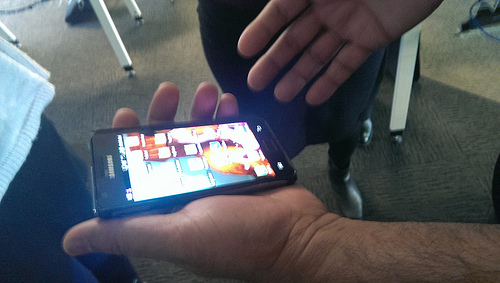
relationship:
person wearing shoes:
[192, 14, 383, 213] [329, 151, 363, 211]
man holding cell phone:
[73, 157, 479, 277] [70, 87, 341, 217]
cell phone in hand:
[70, 87, 341, 217] [61, 71, 349, 267]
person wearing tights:
[192, 14, 383, 213] [308, 116, 362, 179]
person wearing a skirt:
[192, 14, 383, 213] [174, 14, 372, 141]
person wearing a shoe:
[192, 14, 383, 213] [323, 148, 359, 216]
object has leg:
[347, 18, 428, 137] [361, 28, 430, 150]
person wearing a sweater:
[8, 45, 138, 271] [3, 29, 48, 204]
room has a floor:
[9, 14, 480, 273] [11, 16, 432, 186]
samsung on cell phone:
[90, 148, 127, 191] [70, 87, 341, 217]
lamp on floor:
[0, 5, 64, 34] [11, 16, 432, 186]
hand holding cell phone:
[61, 71, 349, 267] [70, 87, 341, 217]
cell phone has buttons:
[70, 87, 341, 217] [258, 108, 310, 179]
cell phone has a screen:
[70, 87, 341, 217] [117, 114, 243, 204]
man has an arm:
[73, 157, 479, 277] [259, 195, 490, 283]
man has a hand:
[73, 157, 479, 277] [61, 71, 349, 267]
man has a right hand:
[73, 157, 479, 277] [209, 1, 416, 96]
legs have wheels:
[8, 5, 168, 78] [87, 7, 174, 81]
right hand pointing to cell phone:
[209, 1, 416, 96] [70, 87, 341, 217]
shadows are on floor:
[54, 17, 196, 149] [11, 16, 432, 186]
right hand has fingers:
[209, 1, 416, 96] [196, 6, 379, 101]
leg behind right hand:
[361, 28, 430, 150] [209, 1, 416, 96]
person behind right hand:
[192, 14, 383, 213] [209, 1, 416, 96]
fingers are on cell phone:
[78, 71, 276, 129] [70, 87, 341, 217]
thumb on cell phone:
[51, 203, 147, 269] [70, 87, 341, 217]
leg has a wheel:
[361, 28, 430, 150] [364, 115, 412, 152]